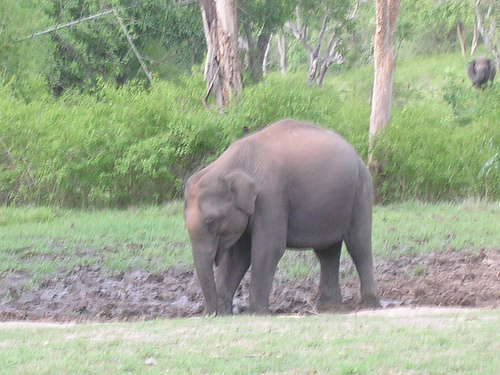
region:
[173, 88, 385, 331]
an elephant grazing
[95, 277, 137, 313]
black dirt behind the elephant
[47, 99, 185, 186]
a thicket of green bushes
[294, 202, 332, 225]
gray wrinkled skin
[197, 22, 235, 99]
a decaying tree trunk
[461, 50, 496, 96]
an elephant walking in the forest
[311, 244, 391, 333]
two sturdy gray hind legs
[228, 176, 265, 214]
a big floppy gray ear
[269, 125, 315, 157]
a patch of discolored skin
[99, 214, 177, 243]
green grass next to the elephant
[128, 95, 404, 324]
elephant on the ground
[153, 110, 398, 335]
gray elephant on the grass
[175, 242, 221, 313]
trunk of the elephant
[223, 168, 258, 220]
ear of the elephant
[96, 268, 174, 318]
brown dirt on ground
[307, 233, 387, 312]
two legs on back of elephant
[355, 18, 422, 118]
tree behind elephant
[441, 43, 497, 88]
elephant in the background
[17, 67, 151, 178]
green bushes behind elephant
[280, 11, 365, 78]
tree with many branches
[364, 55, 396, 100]
stem of a tree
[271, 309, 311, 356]
part of some grass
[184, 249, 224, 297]
part of a trunk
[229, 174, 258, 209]
ear of an elephant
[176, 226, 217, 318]
part of a trunk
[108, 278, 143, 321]
part of some mud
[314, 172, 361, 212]
part of a stomach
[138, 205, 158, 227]
part of some grass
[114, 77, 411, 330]
elephant in grass field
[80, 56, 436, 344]
big elephant in grass field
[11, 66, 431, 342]
large elephant in grass field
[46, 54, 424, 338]
huge elephant in grass field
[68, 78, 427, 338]
mighty elephant in grass field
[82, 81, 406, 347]
big elephant in grass field during daytime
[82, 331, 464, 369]
patch of green grass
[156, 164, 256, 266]
head of an elephant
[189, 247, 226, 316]
trunk of an elephant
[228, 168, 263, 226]
ear of an elephant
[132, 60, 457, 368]
a baby elephant alone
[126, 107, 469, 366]
elephant plays in mud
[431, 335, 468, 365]
grass is very green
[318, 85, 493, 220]
the trunk of a tree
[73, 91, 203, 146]
the leaves are green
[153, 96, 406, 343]
the baby elephant is grey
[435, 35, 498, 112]
another elephant is watching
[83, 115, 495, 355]
there is a lot of mud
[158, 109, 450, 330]
the elephant is young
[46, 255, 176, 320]
the mud is brown